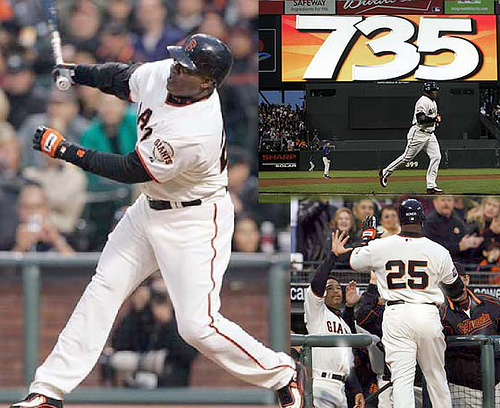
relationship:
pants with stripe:
[27, 188, 297, 395] [204, 197, 262, 369]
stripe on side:
[204, 197, 262, 369] [205, 173, 298, 374]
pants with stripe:
[386, 125, 448, 187] [205, 201, 295, 371]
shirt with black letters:
[131, 59, 235, 203] [132, 100, 173, 170]